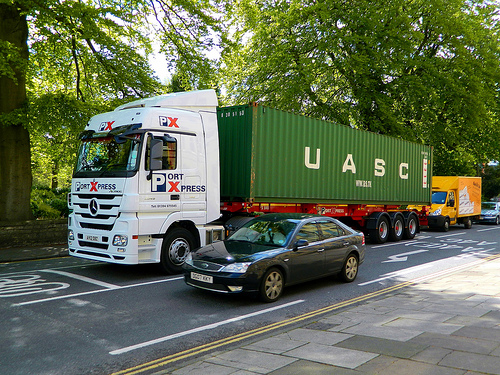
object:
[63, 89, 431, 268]
big truck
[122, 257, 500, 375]
side walk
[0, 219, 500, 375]
road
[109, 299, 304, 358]
line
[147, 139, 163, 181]
mirror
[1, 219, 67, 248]
wall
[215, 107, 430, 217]
shipping contianer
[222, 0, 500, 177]
tree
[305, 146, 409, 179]
uasc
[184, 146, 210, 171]
white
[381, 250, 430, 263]
arrow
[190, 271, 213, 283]
license plate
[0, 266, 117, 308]
bike lane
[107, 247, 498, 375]
lines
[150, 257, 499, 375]
pavement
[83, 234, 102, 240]
license plate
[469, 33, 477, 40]
leaf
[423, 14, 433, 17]
leaf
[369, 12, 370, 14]
leaf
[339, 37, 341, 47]
leaf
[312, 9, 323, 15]
leaf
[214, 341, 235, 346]
line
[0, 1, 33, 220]
tree trunk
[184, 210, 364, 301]
car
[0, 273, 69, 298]
symbol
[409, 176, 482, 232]
van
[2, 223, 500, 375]
street